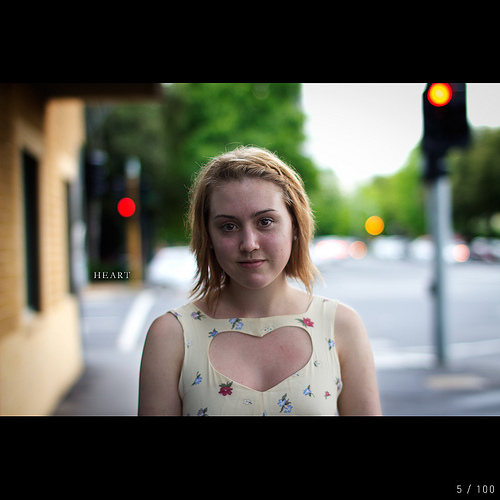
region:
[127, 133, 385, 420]
Woman is blonde.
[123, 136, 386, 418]
Woman has a dress.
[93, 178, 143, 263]
Red light of traffic light.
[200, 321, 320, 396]
Heart opening on dress.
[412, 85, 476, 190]
Traffic light is red.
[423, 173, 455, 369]
Pole of traffic light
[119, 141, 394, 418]
Woman is white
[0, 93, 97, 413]
Building on left side of woman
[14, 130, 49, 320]
Window of building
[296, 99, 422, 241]
Trees in the background.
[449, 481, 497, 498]
Numbers depicting five out of one hundred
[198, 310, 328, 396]
Heart shaped pattern in woman's top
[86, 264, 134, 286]
The word heart in capital letters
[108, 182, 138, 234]
Red light blurred in background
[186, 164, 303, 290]
Woman looking at the camera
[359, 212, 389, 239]
Yellow light blurred in the background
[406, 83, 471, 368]
Blurry traffic light and pole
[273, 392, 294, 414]
Blue flower pattern on woman's top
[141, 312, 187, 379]
Woman's bare right shoulder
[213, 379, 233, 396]
Red flower on woman's top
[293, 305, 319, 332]
The red flower on shoulder.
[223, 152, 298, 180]
The braid in her hair.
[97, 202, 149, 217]
Red stop light behind her.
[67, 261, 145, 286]
Word heart next to the woman.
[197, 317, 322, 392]
heart cut out in her dress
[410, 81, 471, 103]
closest yellow light to the girl.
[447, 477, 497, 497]
5/100 the shutter speed.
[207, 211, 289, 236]
Her two brown eyes.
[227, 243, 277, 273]
Her nose and mouth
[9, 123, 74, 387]
The brick building beside the woman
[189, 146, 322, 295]
young woman's face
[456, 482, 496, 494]
numbers 5/100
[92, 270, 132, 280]
the word HEART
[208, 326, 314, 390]
heart shape in the girl's dress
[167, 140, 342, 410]
girl wearing a sleeveless dress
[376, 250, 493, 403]
blurry street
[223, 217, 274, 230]
two brown eyes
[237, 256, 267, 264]
girl's closed mouth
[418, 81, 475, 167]
red traffic light behind the girl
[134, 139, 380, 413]
girl standing outside near a street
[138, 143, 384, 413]
Girl with braid and heart cut out in shirt.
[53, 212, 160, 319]
Heart spelled out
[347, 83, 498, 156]
Traffic light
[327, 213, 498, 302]
Traffic in the city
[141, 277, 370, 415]
Shirt with flowers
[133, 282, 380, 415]
Shirt with heart cut out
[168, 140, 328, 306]
Girl with strawberry blonde hair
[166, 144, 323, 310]
Girl with brown eyes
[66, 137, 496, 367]
Girl in the city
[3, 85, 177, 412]
Building with windows